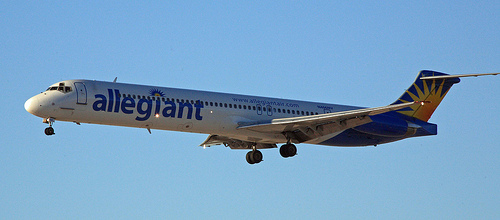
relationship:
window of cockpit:
[65, 88, 69, 90] [50, 80, 71, 99]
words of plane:
[88, 74, 199, 117] [22, 27, 484, 201]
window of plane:
[65, 88, 69, 90] [22, 27, 484, 201]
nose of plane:
[22, 66, 84, 119] [22, 27, 484, 201]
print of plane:
[91, 88, 206, 122] [22, 27, 484, 201]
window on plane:
[65, 88, 69, 90] [22, 27, 484, 201]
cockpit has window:
[50, 80, 71, 99] [65, 88, 69, 90]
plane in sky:
[22, 27, 484, 201] [171, 31, 244, 58]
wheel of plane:
[204, 145, 303, 168] [22, 27, 484, 201]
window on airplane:
[65, 88, 69, 90] [22, 69, 500, 165]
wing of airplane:
[220, 51, 464, 173] [22, 69, 500, 165]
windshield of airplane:
[39, 66, 95, 102] [22, 69, 500, 165]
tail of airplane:
[350, 59, 490, 163] [22, 69, 500, 165]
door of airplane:
[76, 77, 95, 105] [22, 69, 500, 165]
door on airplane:
[76, 77, 95, 105] [22, 69, 500, 165]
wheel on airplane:
[204, 145, 303, 168] [22, 69, 500, 165]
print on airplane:
[91, 88, 206, 122] [22, 69, 500, 165]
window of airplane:
[65, 88, 69, 90] [22, 69, 500, 165]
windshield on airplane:
[39, 66, 95, 102] [22, 69, 500, 165]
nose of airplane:
[22, 66, 84, 119] [22, 69, 500, 165]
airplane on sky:
[22, 27, 484, 201] [14, 11, 484, 213]